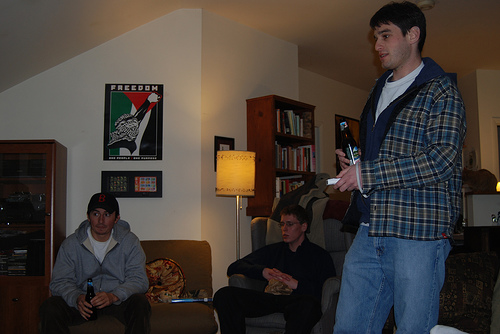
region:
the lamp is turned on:
[215, 149, 256, 196]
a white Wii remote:
[324, 165, 369, 187]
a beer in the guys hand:
[74, 273, 108, 320]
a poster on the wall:
[102, 84, 162, 160]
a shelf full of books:
[245, 92, 316, 214]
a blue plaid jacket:
[362, 73, 461, 238]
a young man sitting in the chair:
[214, 205, 334, 329]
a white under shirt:
[373, 69, 419, 121]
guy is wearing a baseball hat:
[86, 192, 119, 234]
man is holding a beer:
[335, 118, 361, 172]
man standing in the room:
[321, 5, 475, 332]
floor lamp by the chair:
[213, 148, 253, 253]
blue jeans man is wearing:
[336, 232, 446, 332]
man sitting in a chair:
[51, 191, 156, 332]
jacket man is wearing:
[361, 60, 466, 239]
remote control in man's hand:
[326, 176, 338, 187]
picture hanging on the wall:
[105, 82, 162, 160]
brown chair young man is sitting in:
[211, 215, 336, 330]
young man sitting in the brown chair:
[225, 206, 315, 331]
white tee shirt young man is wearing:
[376, 64, 425, 132]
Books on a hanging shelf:
[251, 94, 318, 204]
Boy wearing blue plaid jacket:
[329, 5, 475, 246]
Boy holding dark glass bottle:
[326, 120, 371, 180]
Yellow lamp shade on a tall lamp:
[209, 147, 257, 254]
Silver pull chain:
[237, 196, 244, 212]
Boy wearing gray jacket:
[49, 189, 147, 306]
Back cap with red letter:
[77, 192, 124, 224]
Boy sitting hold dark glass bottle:
[54, 195, 151, 318]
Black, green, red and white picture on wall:
[101, 77, 165, 161]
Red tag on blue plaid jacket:
[436, 227, 451, 244]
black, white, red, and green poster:
[103, 83, 163, 163]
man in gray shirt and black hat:
[40, 190, 151, 332]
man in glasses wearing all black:
[212, 200, 335, 332]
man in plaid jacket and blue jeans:
[322, 0, 464, 332]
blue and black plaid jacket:
[337, 55, 464, 233]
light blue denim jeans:
[332, 222, 449, 332]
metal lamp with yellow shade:
[214, 150, 257, 257]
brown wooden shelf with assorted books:
[243, 93, 318, 216]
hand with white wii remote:
[326, 161, 367, 197]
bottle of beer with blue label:
[337, 113, 362, 168]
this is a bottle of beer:
[329, 103, 378, 193]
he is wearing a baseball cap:
[76, 173, 150, 281]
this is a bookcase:
[245, 75, 340, 210]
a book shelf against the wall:
[236, 68, 338, 228]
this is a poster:
[87, 65, 189, 170]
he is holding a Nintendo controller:
[300, 145, 409, 213]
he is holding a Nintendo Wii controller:
[311, 151, 397, 207]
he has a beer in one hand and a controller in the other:
[301, 97, 393, 224]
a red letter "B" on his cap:
[97, 188, 107, 206]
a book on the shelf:
[281, 146, 291, 161]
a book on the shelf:
[304, 118, 308, 140]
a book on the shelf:
[297, 109, 307, 135]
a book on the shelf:
[285, 96, 293, 136]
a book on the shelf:
[297, 155, 312, 174]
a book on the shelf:
[277, 171, 289, 199]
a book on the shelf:
[270, 146, 297, 174]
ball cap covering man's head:
[79, 189, 122, 216]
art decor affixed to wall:
[101, 82, 166, 202]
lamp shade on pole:
[212, 147, 259, 198]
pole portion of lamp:
[230, 196, 247, 262]